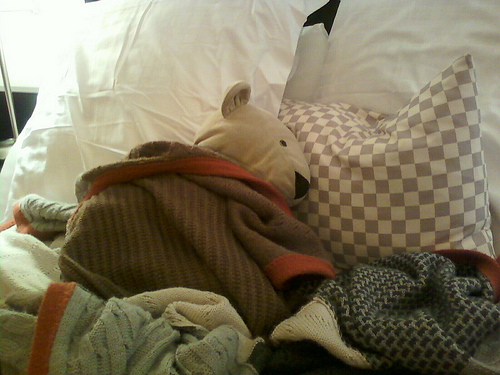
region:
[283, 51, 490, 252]
checkered pillow in bed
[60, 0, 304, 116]
white pillow on the bed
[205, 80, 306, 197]
head of white teddy bear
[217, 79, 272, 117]
the teddy bear's right ear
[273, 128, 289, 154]
the bear's right eye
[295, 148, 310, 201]
the nose on the bear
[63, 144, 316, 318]
brown blanket on the bear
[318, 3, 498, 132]
small white pillow on bed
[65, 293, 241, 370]
blue blanket on bed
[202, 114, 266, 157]
white fur on the bear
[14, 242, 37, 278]
this is a blanket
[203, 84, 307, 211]
this is a toy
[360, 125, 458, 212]
this is a pillow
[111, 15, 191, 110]
this is a pillow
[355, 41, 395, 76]
this is a pillow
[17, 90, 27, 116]
this is a screen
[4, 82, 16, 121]
this is a rod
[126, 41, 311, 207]
this is a stuffed animal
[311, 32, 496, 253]
this is a pillow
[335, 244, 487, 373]
this is a woolen garment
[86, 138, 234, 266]
this is a woolen garment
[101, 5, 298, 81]
this is a white pillow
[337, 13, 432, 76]
this is a white pillow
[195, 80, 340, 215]
this is a white and black stuffed animal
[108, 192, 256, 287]
this is a brown garment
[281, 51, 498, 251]
checkered tan and cream pillow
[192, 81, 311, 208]
a teddy bear relaxes on a pillow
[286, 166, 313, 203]
a black triangular nose of a bear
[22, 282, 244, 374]
a green cable knit blanket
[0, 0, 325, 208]
large white bed pillow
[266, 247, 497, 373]
two tone grey and white knit blanket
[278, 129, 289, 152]
a black button eye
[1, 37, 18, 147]
silver metal bar by white pillow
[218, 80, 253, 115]
round gathered bear ear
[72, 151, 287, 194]
red border on a brown striped blanket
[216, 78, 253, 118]
Ear of a teddy bear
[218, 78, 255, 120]
Ear of a white teddy bear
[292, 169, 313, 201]
Nose of a teddy bear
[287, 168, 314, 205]
Black nose of a teddy bear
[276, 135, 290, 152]
Eye of a teddy bear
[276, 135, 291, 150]
Black eye of a teddy bear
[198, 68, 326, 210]
Head of a teddy bear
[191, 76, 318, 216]
Head of a white teddy bear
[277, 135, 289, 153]
Circular eye of a teddy bear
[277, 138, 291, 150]
Circular black eye of a teddy bear